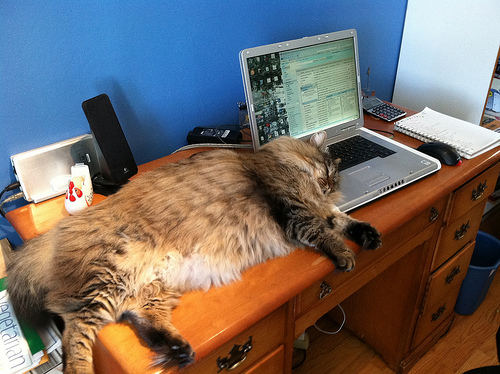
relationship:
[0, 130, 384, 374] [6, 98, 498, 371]
cat on desk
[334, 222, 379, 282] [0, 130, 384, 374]
paw on cat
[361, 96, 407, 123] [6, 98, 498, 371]
calculator on desk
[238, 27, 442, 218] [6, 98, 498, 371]
computer on desk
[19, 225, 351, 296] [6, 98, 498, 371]
cat laying on desk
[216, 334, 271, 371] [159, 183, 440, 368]
handle on drawer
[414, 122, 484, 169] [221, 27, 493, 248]
mouse next to laptop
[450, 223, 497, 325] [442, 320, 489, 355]
waste basket on floor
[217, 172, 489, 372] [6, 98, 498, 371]
brass fittings are on desk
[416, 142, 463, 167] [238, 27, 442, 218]
mouse next to computer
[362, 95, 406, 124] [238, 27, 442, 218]
calculator to right of computer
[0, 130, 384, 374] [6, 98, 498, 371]
cat lying on desk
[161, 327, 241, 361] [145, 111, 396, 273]
foot of cat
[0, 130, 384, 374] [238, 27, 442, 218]
cat resting on computer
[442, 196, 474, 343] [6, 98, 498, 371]
drawers on right of desk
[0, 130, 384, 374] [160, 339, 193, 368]
cat has fur in between toes